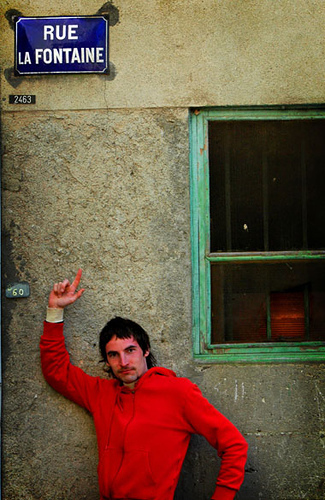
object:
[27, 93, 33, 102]
numbers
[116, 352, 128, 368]
nose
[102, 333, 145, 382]
face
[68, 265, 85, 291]
finger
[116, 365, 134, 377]
mustache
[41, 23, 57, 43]
letter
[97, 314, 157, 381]
hair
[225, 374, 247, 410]
scratches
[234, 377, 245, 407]
marks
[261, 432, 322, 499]
scratches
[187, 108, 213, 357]
side board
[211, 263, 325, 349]
window pane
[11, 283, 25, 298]
number 60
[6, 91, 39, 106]
rectangle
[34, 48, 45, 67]
letter f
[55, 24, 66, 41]
letter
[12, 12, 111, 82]
sign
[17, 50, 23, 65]
letter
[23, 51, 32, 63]
letter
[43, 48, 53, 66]
letter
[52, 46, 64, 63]
letter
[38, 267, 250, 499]
man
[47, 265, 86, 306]
hand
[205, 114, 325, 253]
window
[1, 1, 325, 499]
building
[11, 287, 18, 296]
number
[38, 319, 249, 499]
hoodie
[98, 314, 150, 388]
head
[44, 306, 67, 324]
shirt cuff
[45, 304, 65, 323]
wrist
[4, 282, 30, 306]
block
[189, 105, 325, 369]
frame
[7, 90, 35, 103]
block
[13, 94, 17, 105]
number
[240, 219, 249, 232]
mark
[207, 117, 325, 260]
glass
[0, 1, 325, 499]
wall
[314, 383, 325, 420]
crack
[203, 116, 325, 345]
bars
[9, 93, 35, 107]
sign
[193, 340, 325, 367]
sill